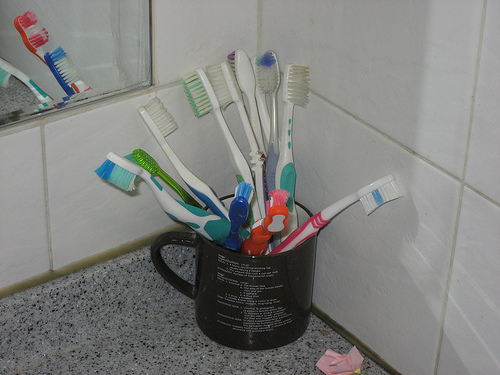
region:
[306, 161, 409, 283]
a pink and white toothbrush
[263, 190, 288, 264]
a red, white and pink toothbrush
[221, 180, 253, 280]
a blue and white toothbrush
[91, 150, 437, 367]
a mug filled with toothbrushes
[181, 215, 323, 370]
a black coffee mug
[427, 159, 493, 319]
white bathroom tile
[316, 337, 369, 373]
a pink piece of paper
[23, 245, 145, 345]
grout around a granite counter top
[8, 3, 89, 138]
a reflection of toothbrushes in the mirror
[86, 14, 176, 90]
a mirror hanging on the wall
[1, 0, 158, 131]
A mirror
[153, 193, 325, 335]
A coffee mug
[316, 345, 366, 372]
crumpled up pink paper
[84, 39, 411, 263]
toothbrushes in the mug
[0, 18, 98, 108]
reflection of the toothbrushes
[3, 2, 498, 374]
A white tiled wall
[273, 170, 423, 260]
A pink and white toothbrush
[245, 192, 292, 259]
an orange and white toothbrush in the mug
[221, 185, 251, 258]
A blue toothbrush in the mug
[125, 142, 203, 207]
A green toothbrush in the mug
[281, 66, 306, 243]
green and white toothbrush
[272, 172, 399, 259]
pink and white toothbrush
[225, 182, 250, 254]
blue tooth brush in cup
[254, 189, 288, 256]
orange and white toothbrush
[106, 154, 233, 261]
green and white toothbrush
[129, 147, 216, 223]
green toothbrush in cup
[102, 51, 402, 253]
toothbrushes in coffee mug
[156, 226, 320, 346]
black and white mug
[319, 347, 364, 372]
pink paper on counter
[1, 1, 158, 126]
mirror on bathroom wall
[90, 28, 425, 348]
a coffee mug with multiple toothbrushes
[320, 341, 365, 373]
a piece of rumpled pink paper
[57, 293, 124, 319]
black specks in the counter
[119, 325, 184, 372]
a gray and black granite countertop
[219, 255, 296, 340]
white writing on a mug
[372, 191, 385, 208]
blue bristles on a toothbrush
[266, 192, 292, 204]
pink bristles on an orange toothbrush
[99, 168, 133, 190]
blue and aqua bristles on a toothbruch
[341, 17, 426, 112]
white tile on the wall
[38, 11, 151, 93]
a mirror on the wall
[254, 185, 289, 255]
Orange tooth brush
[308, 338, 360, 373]
Crumbled piece of pink paper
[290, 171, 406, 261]
Pink tooth brusg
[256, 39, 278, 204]
Clear tooth brush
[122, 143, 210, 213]
Tooth brush with completely lime green 'body'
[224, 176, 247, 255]
Tooth brush with completely blue 'body'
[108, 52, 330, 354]
Black coffee mug full of a dozen toothbrushes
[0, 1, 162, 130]
Mirror with tooth brush relfections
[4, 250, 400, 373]
Granite counter top for bathroom vanity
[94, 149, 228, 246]
Left most toothbrush, Blue and teal in color